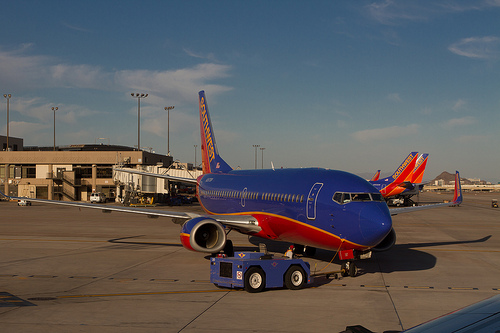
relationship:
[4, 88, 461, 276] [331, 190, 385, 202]
plane has windshield area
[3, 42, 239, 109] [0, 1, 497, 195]
clouds in sky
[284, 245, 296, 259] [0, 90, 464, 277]
man towing plane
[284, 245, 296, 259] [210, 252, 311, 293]
man towing vehicle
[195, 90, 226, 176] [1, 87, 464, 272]
tail wing pulled off aircraft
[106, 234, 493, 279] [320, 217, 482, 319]
shadow on ground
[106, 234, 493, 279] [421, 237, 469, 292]
shadow on ground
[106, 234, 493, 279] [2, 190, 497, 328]
shadow on ground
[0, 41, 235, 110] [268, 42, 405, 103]
clouds in sky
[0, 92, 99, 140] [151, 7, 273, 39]
cloud in sky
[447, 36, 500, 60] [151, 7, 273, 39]
cloud in sky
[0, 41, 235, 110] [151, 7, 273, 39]
clouds in sky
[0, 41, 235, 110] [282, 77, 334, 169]
clouds in sky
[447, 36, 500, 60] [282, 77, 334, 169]
cloud in sky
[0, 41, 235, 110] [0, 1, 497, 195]
clouds in sky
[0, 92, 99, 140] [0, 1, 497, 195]
cloud in sky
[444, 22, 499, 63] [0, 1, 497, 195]
cloud in sky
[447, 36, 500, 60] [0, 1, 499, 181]
cloud in sky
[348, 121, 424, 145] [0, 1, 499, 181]
cloud in sky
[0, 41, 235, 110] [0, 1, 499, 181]
clouds in sky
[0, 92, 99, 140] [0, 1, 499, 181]
cloud in sky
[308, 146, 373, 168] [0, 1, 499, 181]
white cloud in sky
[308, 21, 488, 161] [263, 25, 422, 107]
cloud in sky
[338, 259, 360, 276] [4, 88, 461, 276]
wheels on plane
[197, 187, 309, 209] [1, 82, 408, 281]
windows on plane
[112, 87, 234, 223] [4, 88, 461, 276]
tail of plane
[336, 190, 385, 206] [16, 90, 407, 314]
windshield of plane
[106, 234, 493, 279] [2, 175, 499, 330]
shadow on ground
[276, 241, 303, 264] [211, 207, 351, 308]
man driving vehicle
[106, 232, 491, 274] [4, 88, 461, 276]
shadow of plane